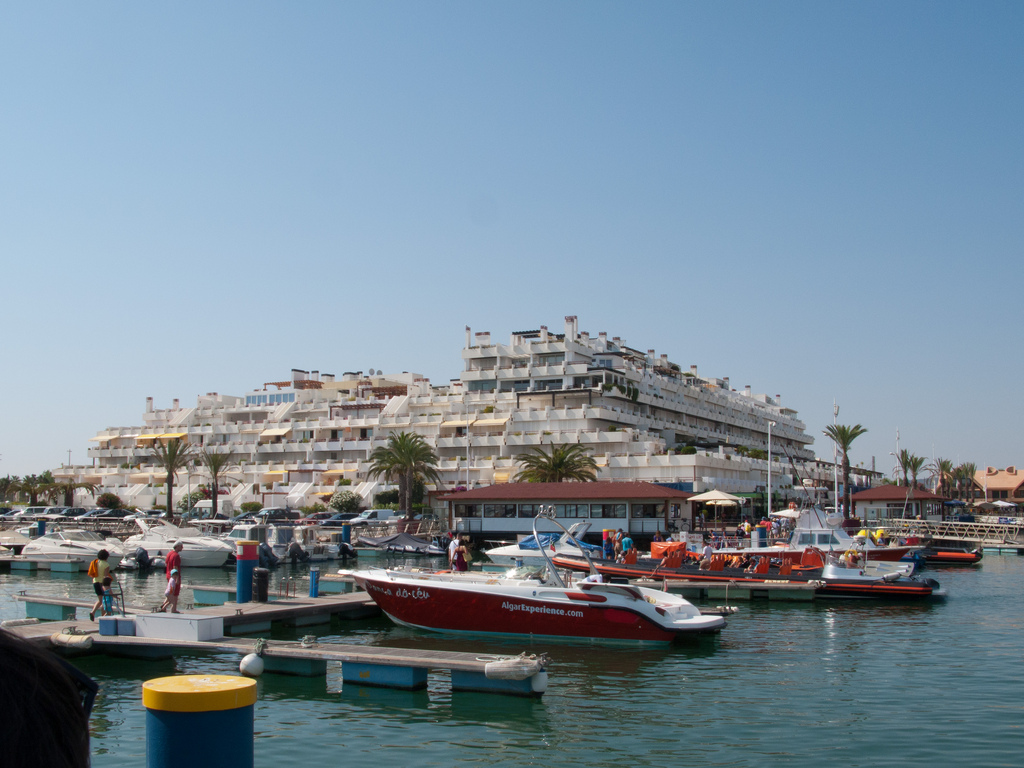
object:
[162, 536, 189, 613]
man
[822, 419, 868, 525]
palm tree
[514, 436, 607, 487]
palm tree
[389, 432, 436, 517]
palm tree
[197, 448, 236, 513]
palm tree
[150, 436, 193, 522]
palm tree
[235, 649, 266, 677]
buoy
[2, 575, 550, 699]
dock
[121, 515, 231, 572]
boat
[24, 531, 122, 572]
boat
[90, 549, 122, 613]
person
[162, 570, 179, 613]
person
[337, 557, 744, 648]
boat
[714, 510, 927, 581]
boat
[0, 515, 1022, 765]
marina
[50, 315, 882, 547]
building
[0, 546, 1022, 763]
water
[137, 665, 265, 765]
post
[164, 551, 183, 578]
red shirt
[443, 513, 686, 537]
wall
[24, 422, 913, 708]
pier